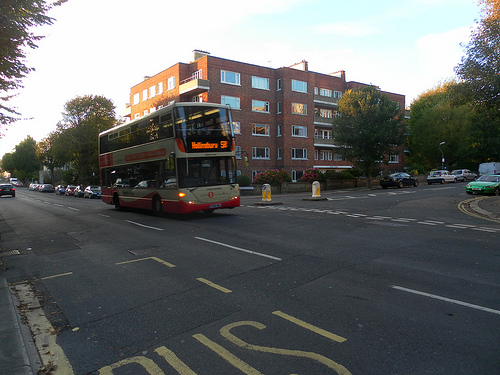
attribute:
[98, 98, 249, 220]
bus — red, beige, double decker, white, double deck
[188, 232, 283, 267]
line — white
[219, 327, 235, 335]
paint — yellow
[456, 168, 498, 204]
car — green, parked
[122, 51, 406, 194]
building — brick, brown, large, red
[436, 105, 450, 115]
leaves — green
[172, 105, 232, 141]
window — rectangular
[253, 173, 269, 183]
flowers — pink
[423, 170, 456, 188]
car — white, parked, silver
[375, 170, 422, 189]
car — black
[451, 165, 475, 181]
sedan — silver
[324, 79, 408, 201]
tree — growing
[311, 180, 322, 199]
trash can — orange, gray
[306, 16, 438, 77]
clouds — white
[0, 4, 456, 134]
sky — blue